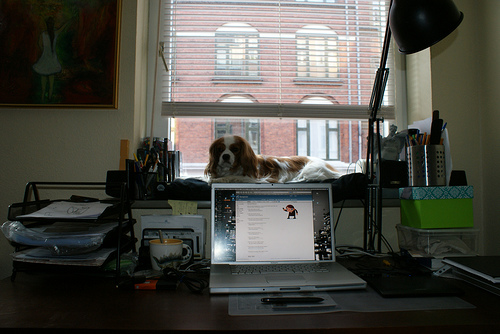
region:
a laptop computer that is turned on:
[207, 180, 368, 292]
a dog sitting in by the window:
[203, 130, 343, 185]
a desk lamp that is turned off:
[357, 1, 466, 286]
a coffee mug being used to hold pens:
[151, 228, 193, 285]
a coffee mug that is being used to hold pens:
[403, 108, 452, 187]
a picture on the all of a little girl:
[1, 0, 118, 110]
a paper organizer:
[7, 179, 140, 286]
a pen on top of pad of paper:
[261, 290, 341, 311]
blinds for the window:
[153, 3, 400, 123]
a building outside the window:
[172, 1, 392, 159]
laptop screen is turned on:
[208, 183, 365, 297]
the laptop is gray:
[197, 177, 371, 297]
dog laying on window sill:
[159, 127, 394, 185]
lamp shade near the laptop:
[168, 0, 472, 307]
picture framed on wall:
[4, 4, 124, 111]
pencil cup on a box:
[393, 125, 486, 222]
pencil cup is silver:
[394, 113, 454, 188]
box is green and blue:
[399, 176, 473, 233]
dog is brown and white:
[209, 129, 347, 186]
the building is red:
[171, 2, 408, 162]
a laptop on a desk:
[199, 171, 369, 296]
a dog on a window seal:
[204, 132, 346, 187]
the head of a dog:
[201, 134, 258, 179]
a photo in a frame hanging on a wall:
[0, 5, 121, 112]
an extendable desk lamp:
[333, 0, 465, 285]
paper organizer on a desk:
[5, 183, 136, 305]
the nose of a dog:
[218, 148, 243, 168]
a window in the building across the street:
[293, 92, 345, 158]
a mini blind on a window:
[159, 0, 389, 121]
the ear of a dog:
[238, 137, 260, 179]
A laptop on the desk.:
[210, 181, 368, 298]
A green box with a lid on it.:
[400, 184, 477, 236]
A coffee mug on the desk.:
[138, 231, 195, 273]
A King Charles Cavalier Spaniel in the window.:
[206, 134, 348, 195]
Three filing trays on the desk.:
[10, 189, 138, 276]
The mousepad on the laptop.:
[252, 267, 317, 285]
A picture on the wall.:
[1, 1, 124, 115]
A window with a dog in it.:
[129, 0, 421, 175]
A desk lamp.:
[359, 1, 470, 303]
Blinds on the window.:
[158, 1, 390, 118]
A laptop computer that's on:
[210, 182, 343, 287]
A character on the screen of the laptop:
[282, 204, 299, 220]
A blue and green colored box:
[402, 187, 478, 229]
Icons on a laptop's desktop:
[221, 193, 233, 239]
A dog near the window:
[210, 135, 336, 175]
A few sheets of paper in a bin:
[49, 200, 101, 217]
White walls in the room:
[38, 123, 94, 166]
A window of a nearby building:
[216, 30, 259, 82]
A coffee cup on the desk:
[152, 240, 191, 259]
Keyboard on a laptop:
[237, 265, 327, 274]